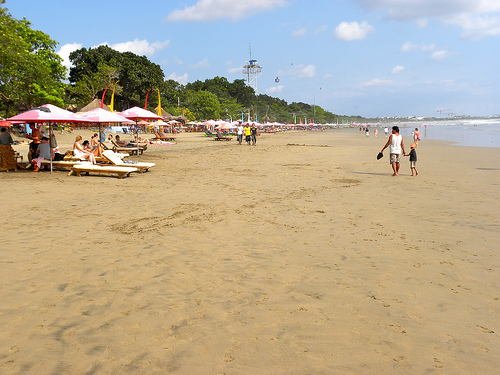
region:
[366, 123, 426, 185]
father and son walking on the beach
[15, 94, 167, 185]
group of people under beach umbrellas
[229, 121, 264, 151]
trio of people walking on the beach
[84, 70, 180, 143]
yellow and red flags on the beach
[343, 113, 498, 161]
shoreline at the beach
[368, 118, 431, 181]
man in white shirt walking with boy in black shirt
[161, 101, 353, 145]
line of umbrellas on the beach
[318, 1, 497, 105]
blue sky with sparse clouds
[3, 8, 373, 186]
tree lined beach front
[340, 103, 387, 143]
group of beach-goers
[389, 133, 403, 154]
white sleeveless tee shirt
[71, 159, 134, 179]
long flat beach chair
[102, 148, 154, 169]
long raised beach chair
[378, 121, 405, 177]
man walking on beach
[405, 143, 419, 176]
boy walking on beach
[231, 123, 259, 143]
group walking on beach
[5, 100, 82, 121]
red and white umbrella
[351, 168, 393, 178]
man's shadow on sand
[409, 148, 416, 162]
dark black tee shirt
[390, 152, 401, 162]
pair of swimming trunks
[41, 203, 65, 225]
tan sand on beach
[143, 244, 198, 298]
tan sand on beach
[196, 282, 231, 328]
tan sand on beach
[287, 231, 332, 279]
tan sand on beach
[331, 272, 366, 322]
tan sand on beach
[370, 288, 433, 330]
tan sand on beach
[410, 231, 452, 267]
tan sand on beach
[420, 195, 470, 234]
tan sand on beach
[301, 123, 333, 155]
tan sand on beach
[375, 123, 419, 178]
Man and boy walking on a beach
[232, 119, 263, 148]
Three people walking on the beach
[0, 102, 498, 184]
Lots of people relaxing on the beach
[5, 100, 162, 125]
Three red and white umbrellas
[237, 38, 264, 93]
Tall white metal tower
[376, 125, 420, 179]
Man holding a boys hand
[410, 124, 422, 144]
Woman in red on the beach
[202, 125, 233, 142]
Two reclining beach chairs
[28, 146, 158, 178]
Four white cushioned reclining beach chairs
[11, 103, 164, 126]
umbrellas are for shade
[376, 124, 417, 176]
man and child walking on the beach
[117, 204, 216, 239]
footprints in the sand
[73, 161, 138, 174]
beach chair laying down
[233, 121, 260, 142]
three people standing together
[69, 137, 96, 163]
woman sitting on the chair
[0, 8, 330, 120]
green trees on the beach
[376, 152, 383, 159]
shoes in the man's hand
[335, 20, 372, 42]
small cloud in the sky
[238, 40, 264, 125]
this seems to be a watch tower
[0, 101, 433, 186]
people are enjoying the beach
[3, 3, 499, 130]
trees grow along the shore line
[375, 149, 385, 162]
the man is carrying something in his left hand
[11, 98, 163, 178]
people are resting under these beach umbrellas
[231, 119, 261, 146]
three people walk along the beach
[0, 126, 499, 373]
the beach has a wide stretch of sand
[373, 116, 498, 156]
it appears the tide is out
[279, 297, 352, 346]
the sand is brown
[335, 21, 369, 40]
clouds in the sky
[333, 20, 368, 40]
a white cloud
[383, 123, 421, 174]
three people walking on the sand